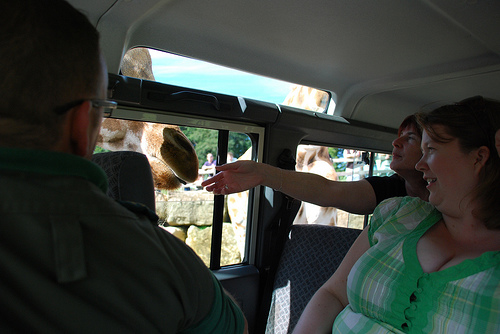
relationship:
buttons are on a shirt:
[407, 278, 426, 306] [375, 195, 417, 314]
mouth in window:
[158, 147, 197, 192] [120, 89, 245, 249]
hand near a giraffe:
[200, 157, 264, 196] [95, 44, 199, 194]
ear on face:
[468, 143, 493, 173] [414, 122, 491, 208]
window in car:
[285, 144, 398, 237] [4, 2, 498, 331]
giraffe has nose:
[93, 48, 195, 188] [157, 129, 199, 181]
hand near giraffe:
[198, 157, 262, 197] [95, 44, 199, 194]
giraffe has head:
[93, 47, 200, 191] [95, 50, 201, 198]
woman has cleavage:
[285, 93, 497, 333] [413, 235, 476, 275]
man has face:
[2, 3, 250, 333] [85, 48, 107, 154]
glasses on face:
[63, 94, 118, 117] [85, 48, 107, 154]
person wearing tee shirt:
[202, 108, 429, 213] [362, 165, 425, 204]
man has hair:
[2, 3, 250, 333] [0, 2, 107, 147]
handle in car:
[106, 67, 281, 130] [4, 2, 500, 334]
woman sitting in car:
[200, 114, 430, 216] [4, 2, 498, 331]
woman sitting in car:
[285, 93, 497, 333] [4, 2, 498, 331]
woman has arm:
[204, 107, 431, 216] [256, 163, 396, 215]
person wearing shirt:
[200, 150, 217, 190] [200, 162, 216, 170]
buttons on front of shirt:
[398, 272, 426, 332] [332, 193, 499, 333]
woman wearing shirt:
[285, 93, 497, 333] [332, 193, 499, 333]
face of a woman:
[416, 119, 475, 209] [285, 93, 497, 333]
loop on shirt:
[47, 212, 90, 284] [2, 137, 250, 331]